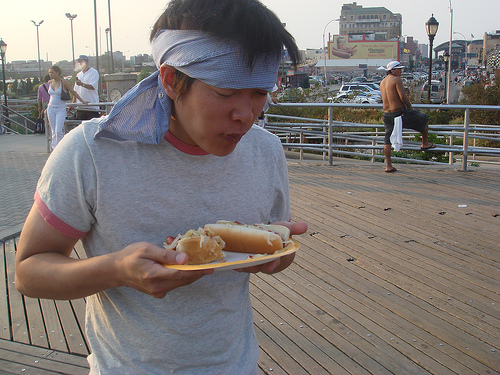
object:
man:
[380, 61, 437, 173]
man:
[73, 55, 100, 120]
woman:
[47, 65, 92, 149]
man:
[11, 0, 290, 375]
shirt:
[33, 115, 291, 375]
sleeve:
[33, 124, 96, 239]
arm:
[15, 241, 213, 300]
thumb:
[160, 249, 189, 264]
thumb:
[290, 222, 308, 234]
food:
[164, 220, 300, 271]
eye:
[211, 89, 236, 98]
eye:
[255, 90, 267, 96]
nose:
[231, 103, 254, 123]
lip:
[218, 133, 246, 142]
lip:
[218, 133, 241, 143]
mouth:
[219, 133, 246, 144]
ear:
[160, 63, 176, 101]